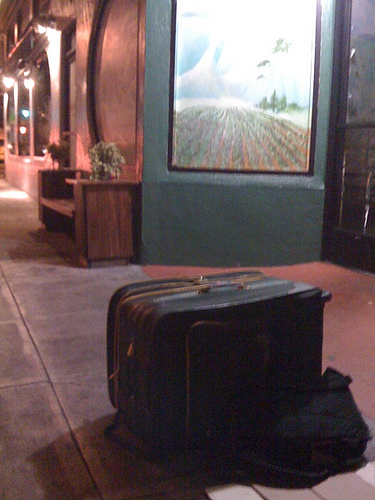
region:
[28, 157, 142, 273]
A brown wooden built in bench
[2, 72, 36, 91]
a streetlight reflected in a window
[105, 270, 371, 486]
blue luggage on the sidewalk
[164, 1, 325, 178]
an agricultrual poster on the wall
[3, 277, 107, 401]
grey concrete paver tiles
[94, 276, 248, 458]
a partially unzipped suitcase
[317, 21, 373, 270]
a large brown wooden door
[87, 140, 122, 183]
a small potted plant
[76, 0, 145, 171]
a section of recessed wall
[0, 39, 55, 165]
windows from the building shining in the night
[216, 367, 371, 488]
Black backpack on the floor.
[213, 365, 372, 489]
Black backpack behind a luggage.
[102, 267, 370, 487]
Black luggage and black backpack.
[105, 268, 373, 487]
Luggage and backpack on the floor.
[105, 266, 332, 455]
Black luggage with tan trim.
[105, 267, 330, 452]
Black luggage in front of a black backpack.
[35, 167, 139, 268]
Brown wooden bench.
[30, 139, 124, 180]
Plants on the arms of a brown bench.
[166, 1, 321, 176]
Portrait on a blue wall.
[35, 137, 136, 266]
Brown bench with potted plants.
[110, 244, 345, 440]
black and brown luggage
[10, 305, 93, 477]
gray colored cement sidewalk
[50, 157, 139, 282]
a wooden bench against wall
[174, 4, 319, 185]
wall art on the street wall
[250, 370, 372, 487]
small black carry on bag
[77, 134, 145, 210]
green plant on arm rest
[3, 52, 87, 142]
row of columns for buildings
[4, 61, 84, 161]
row of street lights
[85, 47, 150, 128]
round art on street wall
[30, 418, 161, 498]
shadow of luggage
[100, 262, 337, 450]
black suitcase with wheels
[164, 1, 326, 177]
poster of farm on a wall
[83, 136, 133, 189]
potted plant on an end table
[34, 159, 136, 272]
long wood bench on a sidewalk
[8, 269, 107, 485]
grey concrete sidewalk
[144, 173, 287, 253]
old building wall painted teal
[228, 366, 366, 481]
black backpack against suitcase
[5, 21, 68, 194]
store front windows on street corner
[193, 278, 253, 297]
brown handle on a black suitcase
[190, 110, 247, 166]
rows of plants in a poster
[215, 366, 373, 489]
small black bag on floor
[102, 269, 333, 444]
square piece of luggage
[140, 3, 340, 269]
green section of wall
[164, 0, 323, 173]
picture on green wall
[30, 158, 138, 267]
wooden bench against wall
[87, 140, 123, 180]
plant on left arm of bench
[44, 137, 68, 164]
plant on right arm of bench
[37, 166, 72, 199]
right arm of bench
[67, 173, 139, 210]
left arm of bench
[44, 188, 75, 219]
seat of the bench